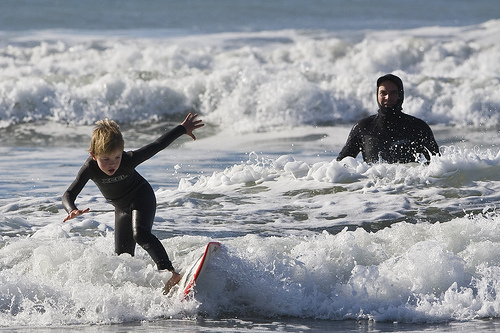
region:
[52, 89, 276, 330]
young child riding surfboard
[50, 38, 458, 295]
father and child in the surf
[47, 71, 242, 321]
water splashing in front of child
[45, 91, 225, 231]
hands opened up wide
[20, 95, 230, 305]
child trying to balance on surfboard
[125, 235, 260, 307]
small foot on tilted surfboard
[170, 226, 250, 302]
red edge on white surfboard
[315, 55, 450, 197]
man chest deep in water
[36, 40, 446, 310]
man and child in black wetsuits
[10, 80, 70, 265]
calm water between two waves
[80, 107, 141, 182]
brown hair sticking up in the back of the head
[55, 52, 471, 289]
water is white and foamy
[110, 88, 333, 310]
water is white and foamy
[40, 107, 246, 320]
boy riding a surfboard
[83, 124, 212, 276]
boy riding a surfboard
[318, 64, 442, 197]
man watching child surf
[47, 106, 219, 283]
blonde haired bow in swimsuit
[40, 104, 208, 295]
blonde haired bow in swimsuit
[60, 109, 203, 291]
a boy on a surfboard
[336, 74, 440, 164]
a man wearing a black wetsuit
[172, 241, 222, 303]
the white and red surfboard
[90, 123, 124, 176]
the head of the boy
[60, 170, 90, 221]
the boy's right arm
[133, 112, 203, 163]
the boy's left arm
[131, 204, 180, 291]
the boy's left leg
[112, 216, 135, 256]
the boy's right leg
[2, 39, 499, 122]
the foamy wave behind the man